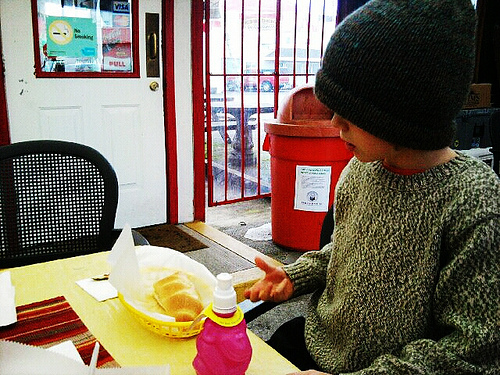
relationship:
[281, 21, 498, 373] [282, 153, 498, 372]
boy wears sweater